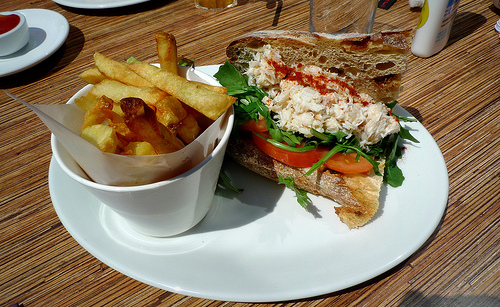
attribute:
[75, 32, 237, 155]
fries — fried, piled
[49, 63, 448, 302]
plate — white, round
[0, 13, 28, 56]
bowl — round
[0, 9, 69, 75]
plate — white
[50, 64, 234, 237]
bowl — white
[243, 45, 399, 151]
meat — white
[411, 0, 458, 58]
bottle — white, yellow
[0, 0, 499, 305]
table — wood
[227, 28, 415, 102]
bread — brown, crusty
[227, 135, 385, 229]
bread — brown, crusty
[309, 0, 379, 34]
bottle — clear, glass, empty